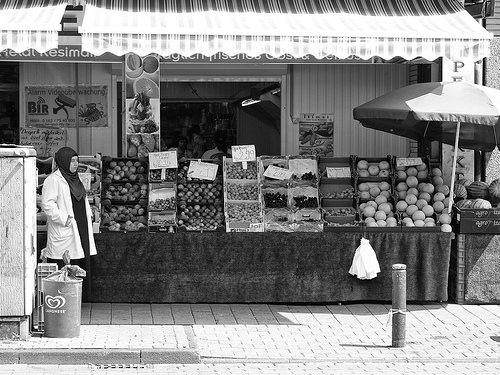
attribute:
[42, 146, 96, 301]
lady — standing, selling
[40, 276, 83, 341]
trash — heart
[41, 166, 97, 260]
coat — white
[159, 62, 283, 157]
window — open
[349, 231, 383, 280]
bags — paper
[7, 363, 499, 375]
road — tiled